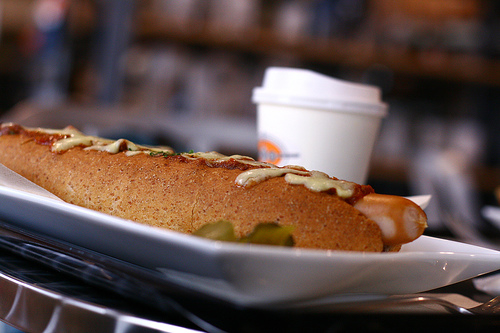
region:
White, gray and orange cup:
[248, 62, 375, 186]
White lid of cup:
[241, 58, 382, 138]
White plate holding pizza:
[34, 194, 286, 301]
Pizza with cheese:
[12, 120, 457, 270]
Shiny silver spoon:
[333, 280, 498, 325]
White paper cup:
[244, 63, 396, 170]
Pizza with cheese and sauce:
[3, 117, 460, 272]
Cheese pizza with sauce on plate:
[23, 126, 457, 279]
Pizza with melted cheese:
[21, 128, 448, 288]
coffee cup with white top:
[243, 59, 376, 172]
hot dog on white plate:
[55, 122, 430, 248]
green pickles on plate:
[201, 212, 288, 251]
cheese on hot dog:
[159, 136, 360, 220]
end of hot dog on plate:
[335, 183, 418, 248]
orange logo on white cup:
[234, 129, 302, 160]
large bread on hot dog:
[105, 137, 255, 207]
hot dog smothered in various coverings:
[72, 129, 412, 251]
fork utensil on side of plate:
[316, 289, 494, 321]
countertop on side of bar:
[14, 207, 159, 328]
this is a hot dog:
[109, 164, 436, 214]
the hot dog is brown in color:
[84, 139, 286, 220]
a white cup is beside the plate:
[255, 72, 375, 157]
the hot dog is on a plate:
[226, 255, 386, 300]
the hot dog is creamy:
[225, 165, 360, 195]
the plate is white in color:
[275, 255, 351, 300]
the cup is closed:
[247, 88, 379, 158]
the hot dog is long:
[7, 157, 380, 219]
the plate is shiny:
[443, 243, 475, 275]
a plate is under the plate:
[444, 294, 496, 320]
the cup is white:
[255, 46, 365, 199]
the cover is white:
[229, 51, 406, 121]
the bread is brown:
[19, 114, 403, 258]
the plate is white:
[7, 121, 483, 312]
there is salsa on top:
[17, 114, 371, 220]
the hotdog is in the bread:
[95, 129, 444, 246]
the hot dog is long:
[10, 101, 415, 307]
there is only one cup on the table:
[241, 39, 400, 219]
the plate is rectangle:
[0, 86, 459, 324]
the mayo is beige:
[55, 124, 356, 218]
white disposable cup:
[250, 65, 387, 195]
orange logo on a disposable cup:
[248, 130, 301, 170]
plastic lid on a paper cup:
[250, 63, 389, 121]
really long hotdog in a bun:
[5, 122, 427, 258]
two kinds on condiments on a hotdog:
[2, 121, 374, 202]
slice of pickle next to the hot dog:
[184, 213, 299, 255]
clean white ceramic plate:
[0, 149, 499, 311]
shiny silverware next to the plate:
[226, 278, 497, 323]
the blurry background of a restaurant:
[1, 3, 496, 229]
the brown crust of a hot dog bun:
[2, 133, 385, 249]